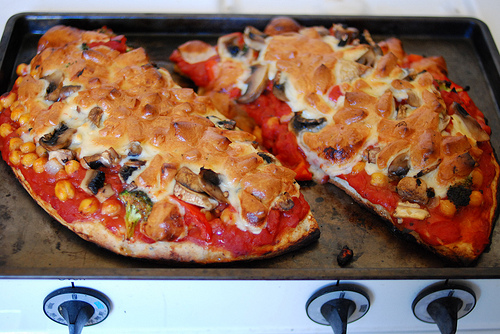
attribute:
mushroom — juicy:
[137, 199, 189, 241]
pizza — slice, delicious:
[1, 19, 325, 268]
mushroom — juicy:
[78, 165, 109, 198]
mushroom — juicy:
[36, 122, 83, 153]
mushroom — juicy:
[197, 162, 233, 206]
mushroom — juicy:
[42, 69, 68, 103]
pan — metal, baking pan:
[0, 9, 499, 283]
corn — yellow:
[78, 195, 101, 215]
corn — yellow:
[52, 175, 77, 204]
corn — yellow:
[62, 157, 82, 177]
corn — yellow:
[31, 154, 50, 174]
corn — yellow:
[0, 120, 17, 141]